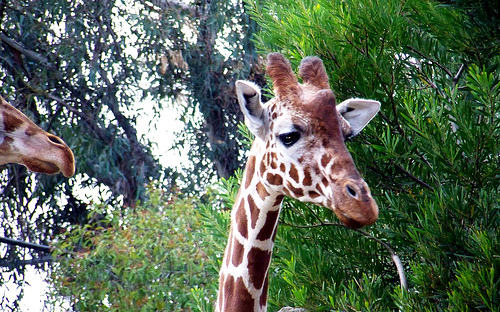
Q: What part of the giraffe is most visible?
A: Head.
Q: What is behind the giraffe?
A: Trees.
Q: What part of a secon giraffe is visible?
A: The nose.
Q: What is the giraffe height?
A: Tall.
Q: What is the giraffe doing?
A: Standing.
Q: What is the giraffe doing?
A: Standing.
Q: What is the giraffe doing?
A: Standing.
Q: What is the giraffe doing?
A: Standing.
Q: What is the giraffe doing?
A: Standing.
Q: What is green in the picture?
A: Trees.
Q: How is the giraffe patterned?
A: In brown spots.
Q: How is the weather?
A: Clear.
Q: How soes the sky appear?
A: White and sunny.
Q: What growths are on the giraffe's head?
A: Horns.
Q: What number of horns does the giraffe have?
A: Two.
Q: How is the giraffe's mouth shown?
A: Closed.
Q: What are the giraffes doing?
A: Standing.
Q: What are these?
A: Giraffes.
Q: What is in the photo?
A: Animals.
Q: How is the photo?
A: Clear.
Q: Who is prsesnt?
A: No one.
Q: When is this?
A: Daytime.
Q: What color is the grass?
A: Green.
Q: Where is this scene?
A: In the zoo.